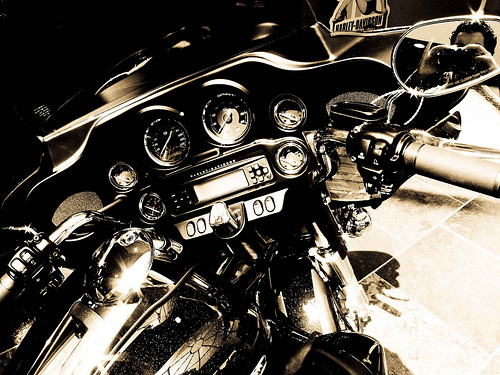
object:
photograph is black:
[1, 1, 499, 374]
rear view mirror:
[391, 12, 499, 99]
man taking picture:
[420, 24, 498, 82]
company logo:
[330, 12, 384, 34]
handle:
[2, 233, 70, 308]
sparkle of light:
[470, 4, 485, 25]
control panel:
[114, 79, 313, 226]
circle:
[201, 97, 254, 144]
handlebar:
[338, 125, 495, 196]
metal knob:
[203, 191, 239, 240]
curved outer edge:
[44, 50, 134, 174]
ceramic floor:
[361, 177, 499, 375]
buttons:
[247, 162, 266, 183]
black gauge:
[264, 93, 307, 135]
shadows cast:
[344, 247, 402, 303]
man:
[410, 14, 499, 77]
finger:
[457, 39, 482, 55]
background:
[286, 3, 496, 37]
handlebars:
[326, 104, 498, 222]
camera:
[426, 37, 466, 77]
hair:
[442, 8, 491, 33]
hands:
[218, 117, 238, 141]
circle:
[258, 136, 345, 189]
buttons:
[161, 205, 322, 243]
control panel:
[105, 152, 405, 245]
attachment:
[63, 238, 206, 340]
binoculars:
[424, 39, 461, 65]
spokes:
[139, 325, 242, 372]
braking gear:
[149, 197, 319, 227]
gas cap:
[63, 255, 167, 323]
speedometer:
[131, 107, 311, 154]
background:
[4, 0, 124, 72]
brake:
[16, 217, 86, 319]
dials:
[91, 88, 358, 231]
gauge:
[142, 109, 289, 164]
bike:
[58, 68, 447, 369]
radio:
[175, 154, 276, 204]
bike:
[6, 12, 483, 365]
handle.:
[54, 78, 465, 219]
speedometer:
[140, 118, 192, 160]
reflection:
[422, 33, 478, 51]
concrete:
[400, 211, 480, 326]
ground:
[395, 247, 483, 373]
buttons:
[160, 199, 286, 238]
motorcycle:
[14, 25, 481, 365]